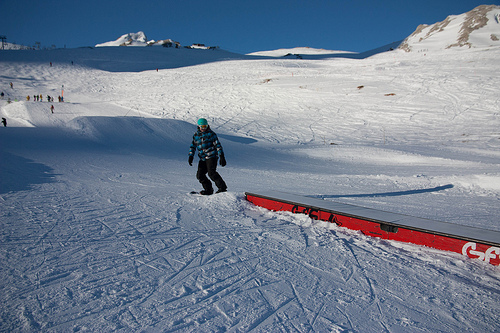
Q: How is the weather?
A: Cold and clear.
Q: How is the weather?
A: Cold.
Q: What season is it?
A: Winter.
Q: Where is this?
A: A ski slope.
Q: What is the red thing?
A: A ski jump.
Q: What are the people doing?
A: Skiing.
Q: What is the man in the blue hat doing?
A: Snowboarding.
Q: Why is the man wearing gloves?
A: So he won't get frostbite.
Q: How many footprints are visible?
A: None.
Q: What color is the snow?
A: White.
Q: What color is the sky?
A: Blue.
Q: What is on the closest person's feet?
A: Snowboard.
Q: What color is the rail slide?
A: Red.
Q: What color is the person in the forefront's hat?
A: Teal.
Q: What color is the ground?
A: Snow.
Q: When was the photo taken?
A: Daytime.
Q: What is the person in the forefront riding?
A: A snowboard.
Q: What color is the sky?
A: Blue.